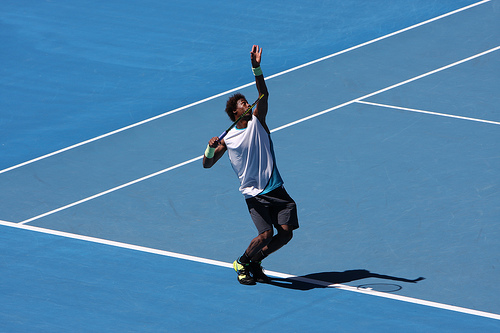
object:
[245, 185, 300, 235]
shorts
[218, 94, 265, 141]
racket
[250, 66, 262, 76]
wrist band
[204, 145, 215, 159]
wrist band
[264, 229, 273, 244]
knees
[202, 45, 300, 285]
tennis player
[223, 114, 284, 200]
jersey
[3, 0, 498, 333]
markings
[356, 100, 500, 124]
white strip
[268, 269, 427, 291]
shadow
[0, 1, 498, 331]
blue ground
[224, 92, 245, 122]
hair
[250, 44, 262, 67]
hand